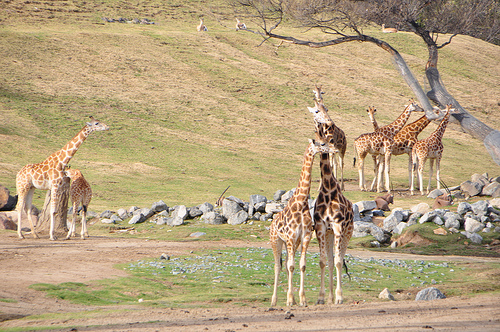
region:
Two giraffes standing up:
[12, 106, 116, 256]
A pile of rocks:
[141, 198, 283, 232]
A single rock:
[409, 276, 449, 311]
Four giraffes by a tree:
[349, 88, 469, 164]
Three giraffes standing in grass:
[256, 97, 352, 296]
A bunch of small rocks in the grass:
[152, 248, 254, 281]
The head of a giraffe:
[75, 101, 115, 137]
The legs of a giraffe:
[264, 246, 312, 316]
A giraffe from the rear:
[70, 180, 93, 238]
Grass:
[132, 138, 212, 184]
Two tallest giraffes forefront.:
[266, 96, 361, 313]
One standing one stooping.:
[8, 102, 109, 246]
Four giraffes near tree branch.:
[353, 97, 459, 195]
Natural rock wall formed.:
[106, 195, 271, 233]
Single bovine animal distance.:
[374, 15, 404, 43]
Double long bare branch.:
[234, 6, 499, 94]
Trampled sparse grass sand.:
[120, 245, 270, 300]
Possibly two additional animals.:
[193, 8, 253, 34]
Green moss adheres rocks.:
[388, 213, 498, 258]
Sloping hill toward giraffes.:
[100, 40, 292, 172]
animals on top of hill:
[189, 11, 256, 37]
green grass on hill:
[142, 121, 259, 169]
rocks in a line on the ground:
[139, 181, 284, 235]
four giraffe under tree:
[352, 101, 448, 187]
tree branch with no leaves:
[272, 8, 358, 55]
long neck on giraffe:
[60, 133, 89, 169]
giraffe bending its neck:
[66, 161, 97, 195]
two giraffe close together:
[268, 133, 358, 314]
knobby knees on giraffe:
[283, 255, 310, 280]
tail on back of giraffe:
[339, 257, 353, 284]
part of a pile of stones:
[433, 202, 483, 234]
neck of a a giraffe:
[298, 172, 311, 199]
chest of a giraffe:
[315, 195, 331, 233]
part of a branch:
[376, 43, 421, 88]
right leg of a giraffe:
[284, 259, 297, 296]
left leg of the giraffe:
[297, 258, 309, 284]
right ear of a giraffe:
[308, 134, 320, 149]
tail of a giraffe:
[338, 257, 351, 285]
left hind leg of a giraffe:
[415, 165, 425, 187]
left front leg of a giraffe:
[328, 239, 346, 281]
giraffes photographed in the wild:
[19, 56, 470, 315]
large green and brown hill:
[29, 0, 369, 197]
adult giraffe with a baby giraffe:
[2, 96, 128, 248]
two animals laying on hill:
[185, 3, 270, 53]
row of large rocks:
[152, 185, 474, 230]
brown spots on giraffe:
[27, 160, 57, 180]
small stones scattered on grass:
[135, 243, 261, 273]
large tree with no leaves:
[248, 8, 484, 115]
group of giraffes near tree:
[352, 85, 473, 202]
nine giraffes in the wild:
[17, 75, 464, 313]